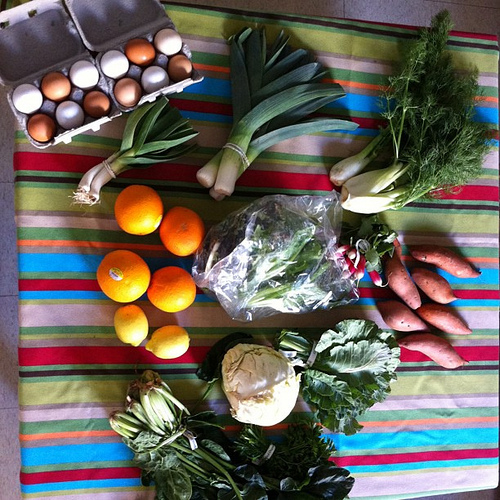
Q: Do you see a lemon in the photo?
A: Yes, there are lemons.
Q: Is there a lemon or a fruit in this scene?
A: Yes, there are lemons.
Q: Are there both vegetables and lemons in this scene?
A: Yes, there are both lemons and vegetables.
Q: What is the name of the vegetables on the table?
A: The vegetables are lemons.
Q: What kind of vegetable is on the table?
A: The vegetables are lemons.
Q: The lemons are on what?
A: The lemons are on the table.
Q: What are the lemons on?
A: The lemons are on the table.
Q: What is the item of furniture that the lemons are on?
A: The piece of furniture is a table.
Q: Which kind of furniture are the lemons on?
A: The lemons are on the table.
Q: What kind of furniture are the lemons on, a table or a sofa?
A: The lemons are on a table.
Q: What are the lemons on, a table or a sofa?
A: The lemons are on a table.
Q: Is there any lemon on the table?
A: Yes, there are lemons on the table.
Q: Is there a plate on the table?
A: No, there are lemons on the table.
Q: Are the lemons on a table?
A: Yes, the lemons are on a table.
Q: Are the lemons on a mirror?
A: No, the lemons are on a table.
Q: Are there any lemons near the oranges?
A: Yes, there are lemons near the oranges.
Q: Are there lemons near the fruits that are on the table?
A: Yes, there are lemons near the oranges.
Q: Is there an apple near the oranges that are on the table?
A: No, there are lemons near the oranges.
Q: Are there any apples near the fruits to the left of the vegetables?
A: No, there are lemons near the oranges.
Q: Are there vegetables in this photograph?
A: Yes, there are vegetables.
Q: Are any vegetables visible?
A: Yes, there are vegetables.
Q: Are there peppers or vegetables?
A: Yes, there are vegetables.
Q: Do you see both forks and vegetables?
A: No, there are vegetables but no forks.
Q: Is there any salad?
A: No, there is no salad.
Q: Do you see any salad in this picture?
A: No, there is no salad.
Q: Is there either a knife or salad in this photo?
A: No, there are no salad or knives.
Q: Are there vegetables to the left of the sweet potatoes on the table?
A: Yes, there are vegetables to the left of the sweet potatoes.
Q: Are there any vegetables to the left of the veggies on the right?
A: Yes, there are vegetables to the left of the sweet potatoes.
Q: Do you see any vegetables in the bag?
A: Yes, there are vegetables in the bag.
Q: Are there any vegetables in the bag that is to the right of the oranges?
A: Yes, there are vegetables in the bag.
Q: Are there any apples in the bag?
A: No, there are vegetables in the bag.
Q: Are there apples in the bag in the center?
A: No, there are vegetables in the bag.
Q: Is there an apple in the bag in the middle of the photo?
A: No, there are vegetables in the bag.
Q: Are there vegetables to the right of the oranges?
A: Yes, there are vegetables to the right of the oranges.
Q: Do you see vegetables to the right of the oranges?
A: Yes, there are vegetables to the right of the oranges.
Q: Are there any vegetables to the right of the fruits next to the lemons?
A: Yes, there are vegetables to the right of the oranges.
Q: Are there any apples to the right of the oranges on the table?
A: No, there are vegetables to the right of the oranges.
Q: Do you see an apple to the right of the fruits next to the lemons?
A: No, there are vegetables to the right of the oranges.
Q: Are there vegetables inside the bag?
A: Yes, there are vegetables inside the bag.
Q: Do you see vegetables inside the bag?
A: Yes, there are vegetables inside the bag.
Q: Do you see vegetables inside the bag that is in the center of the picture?
A: Yes, there are vegetables inside the bag.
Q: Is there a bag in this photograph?
A: Yes, there is a bag.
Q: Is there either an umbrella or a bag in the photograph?
A: Yes, there is a bag.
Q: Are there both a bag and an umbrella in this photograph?
A: No, there is a bag but no umbrellas.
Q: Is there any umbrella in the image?
A: No, there are no umbrellas.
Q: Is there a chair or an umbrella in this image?
A: No, there are no umbrellas or chairs.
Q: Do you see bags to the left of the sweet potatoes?
A: Yes, there is a bag to the left of the sweet potatoes.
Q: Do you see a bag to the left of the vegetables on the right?
A: Yes, there is a bag to the left of the sweet potatoes.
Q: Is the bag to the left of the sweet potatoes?
A: Yes, the bag is to the left of the sweet potatoes.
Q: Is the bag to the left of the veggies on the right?
A: Yes, the bag is to the left of the sweet potatoes.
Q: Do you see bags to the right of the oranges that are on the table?
A: Yes, there is a bag to the right of the oranges.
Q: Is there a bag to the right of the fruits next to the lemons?
A: Yes, there is a bag to the right of the oranges.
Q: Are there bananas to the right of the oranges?
A: No, there is a bag to the right of the oranges.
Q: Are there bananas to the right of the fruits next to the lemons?
A: No, there is a bag to the right of the oranges.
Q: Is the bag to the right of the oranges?
A: Yes, the bag is to the right of the oranges.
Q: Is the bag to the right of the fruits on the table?
A: Yes, the bag is to the right of the oranges.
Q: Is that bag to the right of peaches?
A: No, the bag is to the right of the oranges.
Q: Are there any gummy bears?
A: No, there are no gummy bears.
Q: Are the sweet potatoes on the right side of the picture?
A: Yes, the sweet potatoes are on the right of the image.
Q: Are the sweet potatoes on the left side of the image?
A: No, the sweet potatoes are on the right of the image.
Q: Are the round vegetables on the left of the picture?
A: No, the sweet potatoes are on the right of the image.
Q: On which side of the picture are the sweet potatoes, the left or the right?
A: The sweet potatoes are on the right of the image.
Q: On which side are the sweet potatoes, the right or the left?
A: The sweet potatoes are on the right of the image.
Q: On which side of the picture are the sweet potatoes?
A: The sweet potatoes are on the right of the image.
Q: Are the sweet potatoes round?
A: Yes, the sweet potatoes are round.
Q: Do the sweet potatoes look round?
A: Yes, the sweet potatoes are round.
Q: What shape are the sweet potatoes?
A: The sweet potatoes are round.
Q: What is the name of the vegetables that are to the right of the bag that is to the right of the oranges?
A: The vegetables are sweet potatoes.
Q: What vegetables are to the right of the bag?
A: The vegetables are sweet potatoes.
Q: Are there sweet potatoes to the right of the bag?
A: Yes, there are sweet potatoes to the right of the bag.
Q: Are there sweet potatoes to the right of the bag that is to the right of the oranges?
A: Yes, there are sweet potatoes to the right of the bag.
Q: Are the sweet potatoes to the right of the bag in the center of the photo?
A: Yes, the sweet potatoes are to the right of the bag.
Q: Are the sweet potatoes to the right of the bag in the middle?
A: Yes, the sweet potatoes are to the right of the bag.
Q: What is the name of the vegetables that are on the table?
A: The vegetables are sweet potatoes.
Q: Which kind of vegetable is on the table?
A: The vegetables are sweet potatoes.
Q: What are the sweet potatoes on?
A: The sweet potatoes are on the table.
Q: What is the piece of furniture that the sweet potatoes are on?
A: The piece of furniture is a table.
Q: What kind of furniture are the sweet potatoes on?
A: The sweet potatoes are on the table.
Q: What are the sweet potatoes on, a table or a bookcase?
A: The sweet potatoes are on a table.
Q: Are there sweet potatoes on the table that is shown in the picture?
A: Yes, there are sweet potatoes on the table.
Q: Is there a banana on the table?
A: No, there are sweet potatoes on the table.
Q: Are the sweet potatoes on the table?
A: Yes, the sweet potatoes are on the table.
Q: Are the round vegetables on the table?
A: Yes, the sweet potatoes are on the table.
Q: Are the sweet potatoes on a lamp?
A: No, the sweet potatoes are on the table.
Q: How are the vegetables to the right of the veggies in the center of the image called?
A: The vegetables are sweet potatoes.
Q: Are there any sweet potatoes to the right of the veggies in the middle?
A: Yes, there are sweet potatoes to the right of the veggies.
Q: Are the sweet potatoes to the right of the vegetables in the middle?
A: Yes, the sweet potatoes are to the right of the vegetables.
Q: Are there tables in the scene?
A: Yes, there is a table.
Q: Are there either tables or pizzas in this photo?
A: Yes, there is a table.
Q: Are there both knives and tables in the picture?
A: No, there is a table but no knives.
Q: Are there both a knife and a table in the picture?
A: No, there is a table but no knives.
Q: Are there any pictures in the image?
A: No, there are no pictures.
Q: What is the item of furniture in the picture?
A: The piece of furniture is a table.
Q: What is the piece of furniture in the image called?
A: The piece of furniture is a table.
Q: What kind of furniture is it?
A: The piece of furniture is a table.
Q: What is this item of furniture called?
A: That is a table.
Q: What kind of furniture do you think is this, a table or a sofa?
A: That is a table.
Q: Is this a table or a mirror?
A: This is a table.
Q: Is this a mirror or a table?
A: This is a table.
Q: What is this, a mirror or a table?
A: This is a table.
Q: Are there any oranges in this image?
A: Yes, there are oranges.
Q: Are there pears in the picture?
A: No, there are no pears.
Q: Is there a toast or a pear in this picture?
A: No, there are no pears or toasts.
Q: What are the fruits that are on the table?
A: The fruits are oranges.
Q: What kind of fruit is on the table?
A: The fruits are oranges.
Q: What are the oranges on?
A: The oranges are on the table.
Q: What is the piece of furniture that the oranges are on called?
A: The piece of furniture is a table.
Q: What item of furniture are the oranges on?
A: The oranges are on the table.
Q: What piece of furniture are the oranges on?
A: The oranges are on the table.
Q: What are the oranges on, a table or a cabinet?
A: The oranges are on a table.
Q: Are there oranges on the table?
A: Yes, there are oranges on the table.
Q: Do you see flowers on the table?
A: No, there are oranges on the table.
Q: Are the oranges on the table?
A: Yes, the oranges are on the table.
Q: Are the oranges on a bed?
A: No, the oranges are on the table.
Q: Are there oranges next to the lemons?
A: Yes, there are oranges next to the lemons.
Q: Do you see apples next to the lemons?
A: No, there are oranges next to the lemons.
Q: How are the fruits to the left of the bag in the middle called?
A: The fruits are oranges.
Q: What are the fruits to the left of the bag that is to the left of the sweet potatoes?
A: The fruits are oranges.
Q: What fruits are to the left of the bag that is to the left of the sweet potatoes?
A: The fruits are oranges.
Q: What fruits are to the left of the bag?
A: The fruits are oranges.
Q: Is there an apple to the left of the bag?
A: No, there are oranges to the left of the bag.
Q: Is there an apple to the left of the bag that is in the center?
A: No, there are oranges to the left of the bag.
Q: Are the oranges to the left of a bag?
A: Yes, the oranges are to the left of a bag.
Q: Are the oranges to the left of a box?
A: No, the oranges are to the left of a bag.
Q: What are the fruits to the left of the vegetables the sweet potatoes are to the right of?
A: The fruits are oranges.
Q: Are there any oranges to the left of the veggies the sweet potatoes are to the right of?
A: Yes, there are oranges to the left of the vegetables.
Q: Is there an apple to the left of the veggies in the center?
A: No, there are oranges to the left of the vegetables.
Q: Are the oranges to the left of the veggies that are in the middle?
A: Yes, the oranges are to the left of the vegetables.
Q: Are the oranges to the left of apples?
A: No, the oranges are to the left of the vegetables.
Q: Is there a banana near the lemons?
A: No, there are oranges near the lemons.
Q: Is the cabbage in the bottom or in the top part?
A: The cabbage is in the bottom of the image.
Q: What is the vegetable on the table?
A: The vegetable is a cabbage.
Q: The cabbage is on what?
A: The cabbage is on the table.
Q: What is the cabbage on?
A: The cabbage is on the table.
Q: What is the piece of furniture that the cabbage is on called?
A: The piece of furniture is a table.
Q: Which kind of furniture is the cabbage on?
A: The cabbage is on the table.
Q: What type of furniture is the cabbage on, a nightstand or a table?
A: The cabbage is on a table.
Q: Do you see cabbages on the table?
A: Yes, there is a cabbage on the table.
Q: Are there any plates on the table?
A: No, there is a cabbage on the table.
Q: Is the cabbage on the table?
A: Yes, the cabbage is on the table.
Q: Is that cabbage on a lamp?
A: No, the cabbage is on the table.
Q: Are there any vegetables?
A: Yes, there are vegetables.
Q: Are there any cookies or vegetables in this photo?
A: Yes, there are vegetables.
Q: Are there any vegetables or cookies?
A: Yes, there are vegetables.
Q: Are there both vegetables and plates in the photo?
A: No, there are vegetables but no plates.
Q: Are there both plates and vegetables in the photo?
A: No, there are vegetables but no plates.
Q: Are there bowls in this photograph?
A: No, there are no bowls.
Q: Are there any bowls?
A: No, there are no bowls.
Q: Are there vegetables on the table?
A: Yes, there are vegetables on the table.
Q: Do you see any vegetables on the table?
A: Yes, there are vegetables on the table.